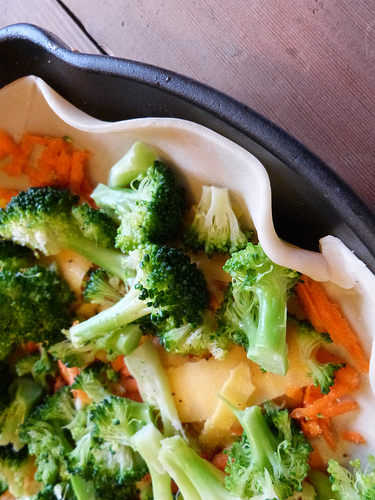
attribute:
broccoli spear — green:
[3, 254, 82, 365]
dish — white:
[17, 60, 372, 337]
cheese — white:
[166, 355, 311, 419]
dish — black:
[34, 80, 221, 170]